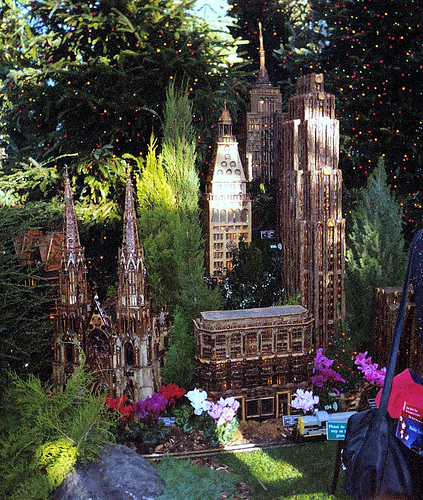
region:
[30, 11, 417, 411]
buildings on display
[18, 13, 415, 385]
buildings that are on display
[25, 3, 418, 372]
buildings on display outside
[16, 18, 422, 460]
outside display of buildings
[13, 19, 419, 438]
outside display of tall buildings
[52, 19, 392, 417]
tall buildings on small display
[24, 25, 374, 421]
tall building displayed small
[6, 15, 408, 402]
tall buildings that are outside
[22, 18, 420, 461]
tall and short buildings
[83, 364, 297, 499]
flowers in fron tof the buildings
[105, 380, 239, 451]
flowers on the ground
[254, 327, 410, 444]
flowers on the ground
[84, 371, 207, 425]
flowers on the ground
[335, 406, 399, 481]
the bag is black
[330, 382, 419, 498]
the bag is black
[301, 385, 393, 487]
the bag is black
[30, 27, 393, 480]
a fairy land city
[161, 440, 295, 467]
gray rail road tracks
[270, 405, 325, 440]
a gray train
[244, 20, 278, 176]
the empire state building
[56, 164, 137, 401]
a double tower church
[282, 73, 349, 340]
a sky scraper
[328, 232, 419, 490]
a womans blue purse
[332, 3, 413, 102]
lots Christmas tree lights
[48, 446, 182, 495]
a large gray rock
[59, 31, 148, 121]
Leaves are green color.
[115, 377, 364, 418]
Flowers are purple, white and pink color.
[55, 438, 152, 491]
Rock is grey color.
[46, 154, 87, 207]
Cross symbol on top of the tower.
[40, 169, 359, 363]
Buildings are white color.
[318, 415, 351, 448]
Board is green and white color.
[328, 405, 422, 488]
Bag is black color.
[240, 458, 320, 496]
Grass is white color.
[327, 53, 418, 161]
Colorful beads are hanging in the tree.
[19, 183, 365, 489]
Day time picture.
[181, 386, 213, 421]
white flowers with green leaves at base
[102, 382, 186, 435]
red and pink flowers in dirt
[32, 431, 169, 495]
grey rock on ground next to flowers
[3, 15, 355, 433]
model of city buildings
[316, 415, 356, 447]
model green and white street sign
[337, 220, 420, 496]
black shoulder leather bag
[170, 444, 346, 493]
green grass in front of model of buildings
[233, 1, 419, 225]
multi -colored lights in tree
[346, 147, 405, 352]
tall green model size evergreen tree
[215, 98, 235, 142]
tower on top of model building